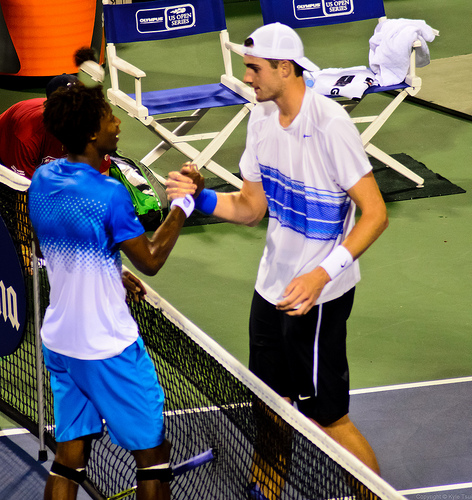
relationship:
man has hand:
[164, 20, 387, 498] [179, 167, 205, 203]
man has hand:
[164, 20, 387, 498] [270, 267, 336, 316]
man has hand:
[25, 81, 205, 498] [166, 158, 203, 207]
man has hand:
[25, 81, 205, 498] [117, 264, 150, 304]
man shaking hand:
[164, 20, 387, 498] [166, 158, 203, 207]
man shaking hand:
[25, 81, 205, 498] [179, 167, 205, 203]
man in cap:
[164, 20, 387, 498] [237, 16, 327, 77]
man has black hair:
[25, 81, 205, 498] [45, 88, 98, 152]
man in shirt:
[25, 81, 205, 498] [27, 160, 145, 360]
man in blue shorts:
[25, 81, 205, 498] [39, 332, 169, 452]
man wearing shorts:
[164, 20, 387, 498] [238, 283, 359, 423]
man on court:
[164, 20, 387, 498] [1, 1, 471, 497]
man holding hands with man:
[164, 20, 387, 498] [25, 81, 205, 498]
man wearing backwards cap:
[164, 20, 387, 498] [241, 22, 320, 72]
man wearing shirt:
[164, 20, 387, 498] [234, 85, 373, 309]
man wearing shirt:
[25, 81, 205, 498] [27, 160, 143, 358]